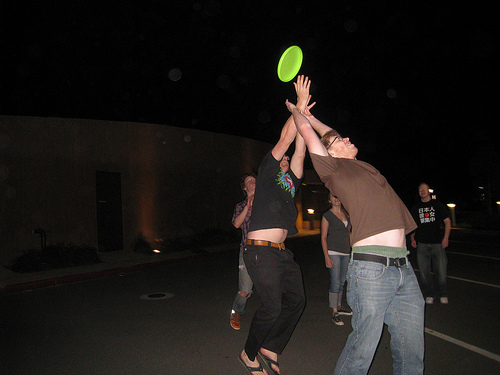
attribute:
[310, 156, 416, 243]
shirt — brown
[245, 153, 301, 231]
shirt — black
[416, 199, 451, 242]
shirt — black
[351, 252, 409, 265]
belt — black, leather, brown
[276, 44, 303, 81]
frisbee — green, round, yellow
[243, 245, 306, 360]
pants — black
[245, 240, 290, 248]
belt — brown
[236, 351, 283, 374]
flip flops — brown, black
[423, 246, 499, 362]
lines — white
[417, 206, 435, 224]
writing — white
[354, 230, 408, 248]
belly — bare, white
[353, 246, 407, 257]
underwear — green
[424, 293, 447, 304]
sneakers — white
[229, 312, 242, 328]
shoe — red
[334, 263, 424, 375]
jeans — blue, light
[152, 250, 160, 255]
light — shining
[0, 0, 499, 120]
sky — dark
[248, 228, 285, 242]
belly — bare, white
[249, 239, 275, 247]
loops — black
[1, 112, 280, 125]
roof — flat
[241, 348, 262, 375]
foot — bare